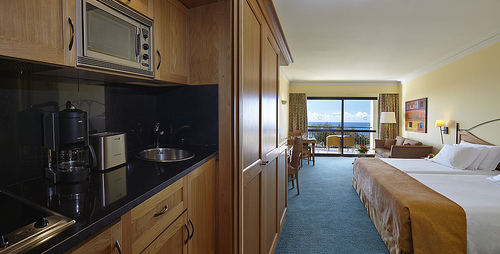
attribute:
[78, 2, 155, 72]
microwave — modern, silver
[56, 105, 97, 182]
coffee maker — electric, here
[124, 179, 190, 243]
drawer — brown, wooden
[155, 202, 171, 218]
handle — metal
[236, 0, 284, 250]
closet — big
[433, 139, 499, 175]
pillows — white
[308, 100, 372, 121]
sky — blue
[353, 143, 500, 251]
beds — well fixed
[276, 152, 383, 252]
floor — blue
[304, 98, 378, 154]
window — large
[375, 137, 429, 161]
sofa — beige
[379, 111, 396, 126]
lamp shade — white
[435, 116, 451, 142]
wall lamp — here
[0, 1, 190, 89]
cabinet doors — wooden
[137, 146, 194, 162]
sink — stainless steel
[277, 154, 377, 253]
carpet — green